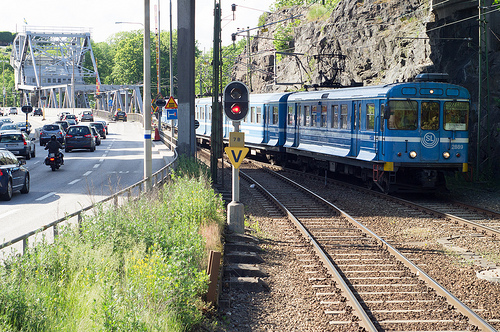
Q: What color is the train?
A: Blue.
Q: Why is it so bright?
A: Sunny.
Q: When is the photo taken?
A: Day time.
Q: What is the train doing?
A: Driving.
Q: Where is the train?
A: The tracks.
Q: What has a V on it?
A: The sign.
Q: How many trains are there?
A: One.